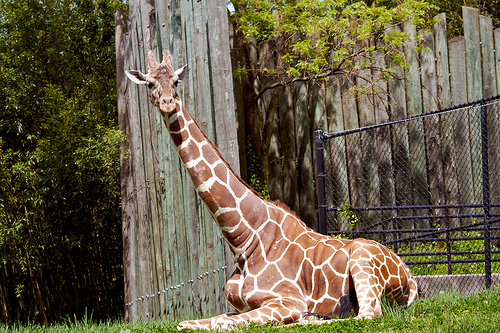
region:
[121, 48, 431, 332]
A giraffe sitting on the ground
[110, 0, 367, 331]
Wooden wall behind the giraffe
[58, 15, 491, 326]
A giraffe in captivity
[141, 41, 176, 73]
Ossicones on giraffe's head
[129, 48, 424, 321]
Brown patten on giraffe's body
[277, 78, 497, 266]
Black fence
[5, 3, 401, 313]
Trees behind the wooden wall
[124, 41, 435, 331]
A giraffe in the zoo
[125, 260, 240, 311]
Nails on the wooden planks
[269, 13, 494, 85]
Uneven height of the wooden planks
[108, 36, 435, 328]
giraffe lying in grass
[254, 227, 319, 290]
brown spots on giraffe fur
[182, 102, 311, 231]
brown giraffe main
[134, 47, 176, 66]
two ossicones on top of giraffe head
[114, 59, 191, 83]
two giraffe ears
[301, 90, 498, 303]
short black metal fence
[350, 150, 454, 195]
chain link material on fence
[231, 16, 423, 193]
short green trees on side of tree trunk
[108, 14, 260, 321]
brown tree trunk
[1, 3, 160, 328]
green foliage and trees on side of brown tree trunk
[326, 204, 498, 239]
the gurad rail behind the fence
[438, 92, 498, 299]
the black chain link fence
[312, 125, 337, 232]
the pole for the black fence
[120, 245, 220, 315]
the nails in the wooden post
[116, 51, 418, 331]
the giraffe laying in the grass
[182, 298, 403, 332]
the legs in the grass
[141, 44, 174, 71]
the horns on the giraffes head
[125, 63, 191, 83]
the ears on the head of the giraffe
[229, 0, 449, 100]
the tree in front of the fence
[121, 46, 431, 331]
the brown giraffe in the kennel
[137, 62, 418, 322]
A giraffe sitting in the grass.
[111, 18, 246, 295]
A wooden pole behind the giraffe.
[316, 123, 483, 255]
A fence on the side of the giraffe.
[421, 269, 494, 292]
A concrete block between the fence.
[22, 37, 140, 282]
Trees behind the wooden pole.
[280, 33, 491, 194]
A wooden building behind the fence.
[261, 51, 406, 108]
The branch of the tree.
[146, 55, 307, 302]
The giraffe is brown and white.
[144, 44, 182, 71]
The giraffe has horns on top of head.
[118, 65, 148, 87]
The giraffe ear is sticking straight up.